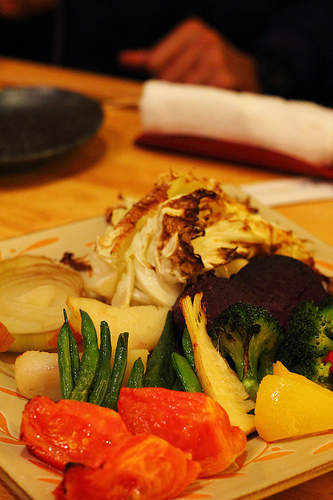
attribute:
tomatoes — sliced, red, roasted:
[91, 406, 196, 482]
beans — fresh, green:
[53, 304, 133, 380]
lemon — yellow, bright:
[214, 345, 309, 419]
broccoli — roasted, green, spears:
[215, 297, 291, 373]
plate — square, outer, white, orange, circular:
[222, 437, 324, 498]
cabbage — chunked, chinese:
[138, 191, 236, 256]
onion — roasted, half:
[13, 247, 90, 313]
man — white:
[144, 12, 238, 89]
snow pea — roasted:
[50, 311, 119, 373]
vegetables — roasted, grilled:
[53, 245, 268, 434]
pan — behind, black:
[24, 100, 103, 167]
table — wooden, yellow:
[95, 133, 158, 187]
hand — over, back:
[139, 28, 191, 58]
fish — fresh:
[77, 402, 113, 446]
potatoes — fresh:
[72, 245, 195, 380]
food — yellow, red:
[33, 395, 169, 465]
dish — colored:
[44, 206, 121, 265]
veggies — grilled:
[79, 194, 313, 403]